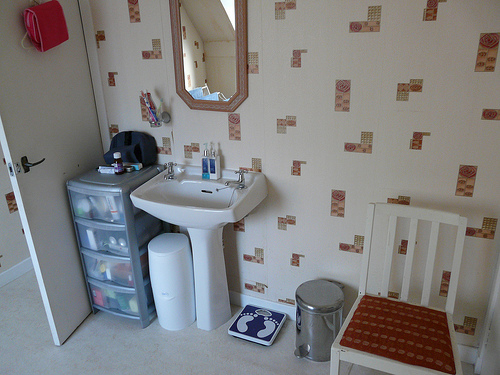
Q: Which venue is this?
A: This is a bathroom.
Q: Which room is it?
A: It is a bathroom.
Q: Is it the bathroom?
A: Yes, it is the bathroom.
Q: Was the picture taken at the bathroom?
A: Yes, it was taken in the bathroom.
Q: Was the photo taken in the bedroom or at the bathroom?
A: It was taken at the bathroom.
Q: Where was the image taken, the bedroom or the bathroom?
A: It was taken at the bathroom.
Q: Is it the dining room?
A: No, it is the bathroom.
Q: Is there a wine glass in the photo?
A: Yes, there is a wine glass.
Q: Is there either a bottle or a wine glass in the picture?
A: Yes, there is a wine glass.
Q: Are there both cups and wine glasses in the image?
A: No, there is a wine glass but no cups.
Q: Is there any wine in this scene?
A: No, there is no wine.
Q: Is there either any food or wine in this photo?
A: No, there are no wine or food.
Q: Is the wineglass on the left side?
A: Yes, the wineglass is on the left of the image.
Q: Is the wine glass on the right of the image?
A: No, the wine glass is on the left of the image.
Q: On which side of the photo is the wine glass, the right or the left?
A: The wine glass is on the left of the image.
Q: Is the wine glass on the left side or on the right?
A: The wine glass is on the left of the image.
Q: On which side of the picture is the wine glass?
A: The wine glass is on the left of the image.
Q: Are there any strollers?
A: No, there are no strollers.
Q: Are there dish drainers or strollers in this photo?
A: No, there are no strollers or dish drainers.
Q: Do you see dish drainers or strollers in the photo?
A: No, there are no strollers or dish drainers.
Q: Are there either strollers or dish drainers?
A: No, there are no strollers or dish drainers.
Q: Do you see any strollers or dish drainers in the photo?
A: No, there are no strollers or dish drainers.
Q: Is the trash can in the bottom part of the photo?
A: Yes, the trash can is in the bottom of the image.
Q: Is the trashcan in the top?
A: No, the trashcan is in the bottom of the image.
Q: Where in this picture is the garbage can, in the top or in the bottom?
A: The garbage can is in the bottom of the image.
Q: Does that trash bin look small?
A: Yes, the trash bin is small.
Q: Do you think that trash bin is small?
A: Yes, the trash bin is small.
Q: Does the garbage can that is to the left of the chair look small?
A: Yes, the garbage can is small.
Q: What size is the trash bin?
A: The trash bin is small.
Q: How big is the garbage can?
A: The garbage can is small.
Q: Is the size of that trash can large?
A: No, the trash can is small.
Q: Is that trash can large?
A: No, the trash can is small.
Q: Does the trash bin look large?
A: No, the trash bin is small.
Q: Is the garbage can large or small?
A: The garbage can is small.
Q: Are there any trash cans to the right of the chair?
A: No, the trash can is to the left of the chair.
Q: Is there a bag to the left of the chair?
A: No, there is a trash can to the left of the chair.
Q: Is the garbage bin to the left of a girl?
A: No, the garbage bin is to the left of the chair.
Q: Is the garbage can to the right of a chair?
A: No, the garbage can is to the left of a chair.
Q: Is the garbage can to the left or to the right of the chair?
A: The garbage can is to the left of the chair.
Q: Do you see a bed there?
A: No, there are no beds.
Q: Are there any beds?
A: No, there are no beds.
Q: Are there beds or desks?
A: No, there are no beds or desks.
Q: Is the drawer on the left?
A: Yes, the drawer is on the left of the image.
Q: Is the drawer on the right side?
A: No, the drawer is on the left of the image.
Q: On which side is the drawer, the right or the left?
A: The drawer is on the left of the image.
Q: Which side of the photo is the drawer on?
A: The drawer is on the left of the image.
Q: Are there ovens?
A: No, there are no ovens.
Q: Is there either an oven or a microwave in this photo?
A: No, there are no ovens or microwaves.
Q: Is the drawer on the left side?
A: Yes, the drawer is on the left of the image.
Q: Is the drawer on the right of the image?
A: No, the drawer is on the left of the image.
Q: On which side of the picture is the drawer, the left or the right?
A: The drawer is on the left of the image.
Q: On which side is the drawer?
A: The drawer is on the left of the image.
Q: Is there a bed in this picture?
A: No, there are no beds.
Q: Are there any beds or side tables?
A: No, there are no beds or side tables.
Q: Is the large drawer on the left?
A: Yes, the drawer is on the left of the image.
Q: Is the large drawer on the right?
A: No, the drawer is on the left of the image.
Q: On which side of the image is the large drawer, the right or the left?
A: The drawer is on the left of the image.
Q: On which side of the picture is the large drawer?
A: The drawer is on the left of the image.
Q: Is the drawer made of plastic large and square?
A: Yes, the drawer is large and square.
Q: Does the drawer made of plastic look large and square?
A: Yes, the drawer is large and square.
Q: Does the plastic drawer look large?
A: Yes, the drawer is large.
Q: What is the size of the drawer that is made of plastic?
A: The drawer is large.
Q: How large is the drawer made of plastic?
A: The drawer is large.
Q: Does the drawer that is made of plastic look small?
A: No, the drawer is large.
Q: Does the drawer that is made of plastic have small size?
A: No, the drawer is large.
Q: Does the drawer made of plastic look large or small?
A: The drawer is large.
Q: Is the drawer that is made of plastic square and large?
A: Yes, the drawer is square and large.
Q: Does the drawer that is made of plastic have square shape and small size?
A: No, the drawer is square but large.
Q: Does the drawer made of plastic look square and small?
A: No, the drawer is square but large.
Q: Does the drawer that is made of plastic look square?
A: Yes, the drawer is square.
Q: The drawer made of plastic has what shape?
A: The drawer is square.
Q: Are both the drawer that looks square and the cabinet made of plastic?
A: Yes, both the drawer and the cabinet are made of plastic.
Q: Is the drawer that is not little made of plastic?
A: Yes, the drawer is made of plastic.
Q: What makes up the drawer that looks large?
A: The drawer is made of plastic.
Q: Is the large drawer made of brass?
A: No, the drawer is made of plastic.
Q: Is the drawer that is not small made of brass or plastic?
A: The drawer is made of plastic.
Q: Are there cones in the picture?
A: No, there are no cones.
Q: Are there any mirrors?
A: Yes, there is a mirror.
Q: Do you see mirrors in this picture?
A: Yes, there is a mirror.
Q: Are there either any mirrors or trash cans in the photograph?
A: Yes, there is a mirror.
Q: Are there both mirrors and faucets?
A: Yes, there are both a mirror and a faucet.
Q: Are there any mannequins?
A: No, there are no mannequins.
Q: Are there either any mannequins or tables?
A: No, there are no mannequins or tables.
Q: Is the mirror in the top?
A: Yes, the mirror is in the top of the image.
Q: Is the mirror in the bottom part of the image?
A: No, the mirror is in the top of the image.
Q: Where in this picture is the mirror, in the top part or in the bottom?
A: The mirror is in the top of the image.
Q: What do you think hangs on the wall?
A: The mirror hangs on the wall.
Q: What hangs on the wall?
A: The mirror hangs on the wall.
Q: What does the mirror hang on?
A: The mirror hangs on the wall.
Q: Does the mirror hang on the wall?
A: Yes, the mirror hangs on the wall.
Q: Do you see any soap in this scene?
A: Yes, there is a soap.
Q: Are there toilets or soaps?
A: Yes, there is a soap.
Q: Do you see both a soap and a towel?
A: No, there is a soap but no towels.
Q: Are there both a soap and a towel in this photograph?
A: No, there is a soap but no towels.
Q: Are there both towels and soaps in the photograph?
A: No, there is a soap but no towels.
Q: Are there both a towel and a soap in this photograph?
A: No, there is a soap but no towels.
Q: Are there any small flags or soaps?
A: Yes, there is a small soap.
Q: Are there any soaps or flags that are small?
A: Yes, the soap is small.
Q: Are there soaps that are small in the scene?
A: Yes, there is a small soap.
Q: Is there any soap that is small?
A: Yes, there is a soap that is small.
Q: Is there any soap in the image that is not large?
A: Yes, there is a small soap.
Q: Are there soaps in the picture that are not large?
A: Yes, there is a small soap.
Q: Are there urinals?
A: No, there are no urinals.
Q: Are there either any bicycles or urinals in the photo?
A: No, there are no urinals or bicycles.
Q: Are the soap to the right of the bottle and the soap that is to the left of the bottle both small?
A: Yes, both the soap and the soap are small.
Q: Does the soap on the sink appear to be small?
A: Yes, the soap is small.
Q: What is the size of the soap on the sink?
A: The soap is small.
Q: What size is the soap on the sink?
A: The soap is small.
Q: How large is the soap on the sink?
A: The soap is small.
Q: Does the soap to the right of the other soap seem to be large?
A: No, the soap is small.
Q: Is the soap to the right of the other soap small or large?
A: The soap is small.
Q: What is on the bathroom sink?
A: The soap is on the sink.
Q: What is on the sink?
A: The soap is on the sink.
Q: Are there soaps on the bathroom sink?
A: Yes, there is a soap on the sink.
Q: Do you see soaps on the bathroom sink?
A: Yes, there is a soap on the sink.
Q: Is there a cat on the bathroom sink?
A: No, there is a soap on the sink.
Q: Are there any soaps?
A: Yes, there is a soap.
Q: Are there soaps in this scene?
A: Yes, there is a soap.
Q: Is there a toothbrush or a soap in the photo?
A: Yes, there is a soap.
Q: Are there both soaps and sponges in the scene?
A: No, there is a soap but no sponges.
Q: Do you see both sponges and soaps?
A: No, there is a soap but no sponges.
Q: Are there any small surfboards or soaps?
A: Yes, there is a small soap.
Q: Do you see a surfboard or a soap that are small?
A: Yes, the soap is small.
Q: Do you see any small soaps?
A: Yes, there is a small soap.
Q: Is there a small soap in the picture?
A: Yes, there is a small soap.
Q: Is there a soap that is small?
A: Yes, there is a soap that is small.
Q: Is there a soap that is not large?
A: Yes, there is a small soap.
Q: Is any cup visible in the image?
A: No, there are no cups.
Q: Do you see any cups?
A: No, there are no cups.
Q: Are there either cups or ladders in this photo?
A: No, there are no cups or ladders.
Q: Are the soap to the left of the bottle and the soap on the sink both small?
A: Yes, both the soap and the soap are small.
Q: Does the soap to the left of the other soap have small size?
A: Yes, the soap is small.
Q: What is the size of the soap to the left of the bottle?
A: The soap is small.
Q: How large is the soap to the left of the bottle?
A: The soap is small.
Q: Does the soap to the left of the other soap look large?
A: No, the soap is small.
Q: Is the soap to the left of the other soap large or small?
A: The soap is small.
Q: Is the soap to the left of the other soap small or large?
A: The soap is small.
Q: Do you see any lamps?
A: No, there are no lamps.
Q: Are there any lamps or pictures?
A: No, there are no lamps or pictures.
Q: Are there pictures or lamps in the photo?
A: No, there are no lamps or pictures.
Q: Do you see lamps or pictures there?
A: No, there are no lamps or pictures.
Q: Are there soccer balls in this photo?
A: No, there are no soccer balls.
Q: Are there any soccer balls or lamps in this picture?
A: No, there are no soccer balls or lamps.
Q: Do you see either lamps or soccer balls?
A: No, there are no soccer balls or lamps.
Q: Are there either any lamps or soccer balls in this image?
A: No, there are no soccer balls or lamps.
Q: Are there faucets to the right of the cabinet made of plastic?
A: Yes, there is a faucet to the right of the cabinet.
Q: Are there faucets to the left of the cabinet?
A: No, the faucet is to the right of the cabinet.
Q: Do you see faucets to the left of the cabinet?
A: No, the faucet is to the right of the cabinet.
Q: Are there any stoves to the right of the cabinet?
A: No, there is a faucet to the right of the cabinet.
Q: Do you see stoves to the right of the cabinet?
A: No, there is a faucet to the right of the cabinet.